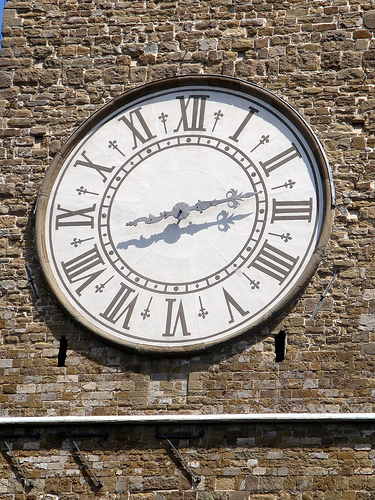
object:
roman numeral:
[270, 197, 313, 224]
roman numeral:
[54, 203, 96, 230]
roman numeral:
[99, 281, 140, 331]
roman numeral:
[246, 238, 300, 286]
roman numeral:
[222, 286, 250, 324]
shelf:
[0, 413, 375, 490]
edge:
[368, 412, 375, 421]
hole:
[274, 329, 288, 364]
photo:
[0, 0, 375, 381]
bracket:
[303, 116, 337, 282]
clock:
[33, 74, 337, 355]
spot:
[273, 326, 288, 363]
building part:
[0, 2, 123, 72]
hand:
[125, 188, 264, 227]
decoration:
[76, 185, 100, 195]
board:
[216, 411, 221, 423]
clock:
[123, 189, 262, 236]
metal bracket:
[154, 422, 204, 483]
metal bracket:
[61, 431, 109, 489]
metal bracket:
[0, 432, 41, 490]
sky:
[109, 150, 258, 253]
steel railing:
[164, 435, 202, 482]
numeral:
[258, 142, 302, 178]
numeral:
[228, 105, 259, 142]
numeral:
[173, 94, 211, 132]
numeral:
[117, 106, 157, 150]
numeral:
[73, 150, 116, 183]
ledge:
[0, 413, 375, 425]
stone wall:
[1, 0, 375, 499]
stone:
[95, 366, 329, 399]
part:
[187, 353, 195, 366]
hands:
[115, 210, 254, 251]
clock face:
[43, 85, 324, 348]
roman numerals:
[162, 297, 192, 337]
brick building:
[2, 1, 374, 497]